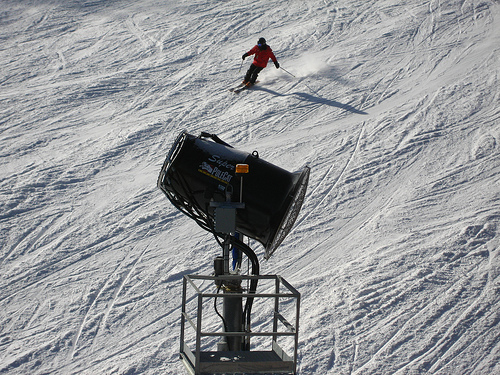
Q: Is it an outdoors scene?
A: Yes, it is outdoors.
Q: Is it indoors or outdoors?
A: It is outdoors.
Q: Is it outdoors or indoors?
A: It is outdoors.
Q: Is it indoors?
A: No, it is outdoors.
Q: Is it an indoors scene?
A: No, it is outdoors.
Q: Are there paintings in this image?
A: No, there are no paintings.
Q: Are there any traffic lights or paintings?
A: No, there are no paintings or traffic lights.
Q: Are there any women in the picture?
A: No, there are no women.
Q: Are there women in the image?
A: No, there are no women.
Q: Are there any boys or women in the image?
A: No, there are no women or boys.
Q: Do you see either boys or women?
A: No, there are no women or boys.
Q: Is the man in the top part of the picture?
A: Yes, the man is in the top of the image.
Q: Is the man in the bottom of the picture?
A: No, the man is in the top of the image.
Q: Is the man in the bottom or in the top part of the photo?
A: The man is in the top of the image.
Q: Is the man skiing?
A: Yes, the man is skiing.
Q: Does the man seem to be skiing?
A: Yes, the man is skiing.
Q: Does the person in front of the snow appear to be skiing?
A: Yes, the man is skiing.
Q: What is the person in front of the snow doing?
A: The man is skiing.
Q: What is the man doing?
A: The man is skiing.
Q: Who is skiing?
A: The man is skiing.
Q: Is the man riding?
A: No, the man is skiing.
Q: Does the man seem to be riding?
A: No, the man is skiing.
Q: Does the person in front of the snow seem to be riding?
A: No, the man is skiing.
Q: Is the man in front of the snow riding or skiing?
A: The man is skiing.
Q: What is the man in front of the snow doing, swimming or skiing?
A: The man is skiing.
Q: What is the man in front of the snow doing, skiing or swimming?
A: The man is skiing.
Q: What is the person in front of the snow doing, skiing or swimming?
A: The man is skiing.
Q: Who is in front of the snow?
A: The man is in front of the snow.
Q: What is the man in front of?
A: The man is in front of the snow.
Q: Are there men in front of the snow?
A: Yes, there is a man in front of the snow.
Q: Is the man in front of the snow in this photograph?
A: Yes, the man is in front of the snow.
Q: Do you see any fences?
A: No, there are no fences.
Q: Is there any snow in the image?
A: Yes, there is snow.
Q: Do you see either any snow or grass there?
A: Yes, there is snow.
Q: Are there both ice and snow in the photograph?
A: Yes, there are both snow and ice.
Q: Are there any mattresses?
A: No, there are no mattresses.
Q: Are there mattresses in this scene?
A: No, there are no mattresses.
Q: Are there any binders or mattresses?
A: No, there are no mattresses or binders.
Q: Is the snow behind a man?
A: Yes, the snow is behind a man.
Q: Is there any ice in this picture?
A: Yes, there is ice.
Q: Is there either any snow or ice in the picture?
A: Yes, there is ice.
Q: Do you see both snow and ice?
A: Yes, there are both ice and snow.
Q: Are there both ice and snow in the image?
A: Yes, there are both ice and snow.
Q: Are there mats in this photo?
A: No, there are no mats.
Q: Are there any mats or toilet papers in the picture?
A: No, there are no mats or toilet papers.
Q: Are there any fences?
A: No, there are no fences.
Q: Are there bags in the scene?
A: No, there are no bags.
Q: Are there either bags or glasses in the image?
A: No, there are no bags or glasses.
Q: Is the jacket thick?
A: Yes, the jacket is thick.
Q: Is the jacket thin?
A: No, the jacket is thick.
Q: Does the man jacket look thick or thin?
A: The jacket is thick.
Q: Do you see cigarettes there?
A: No, there are no cigarettes.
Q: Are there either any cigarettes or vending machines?
A: No, there are no cigarettes or vending machines.